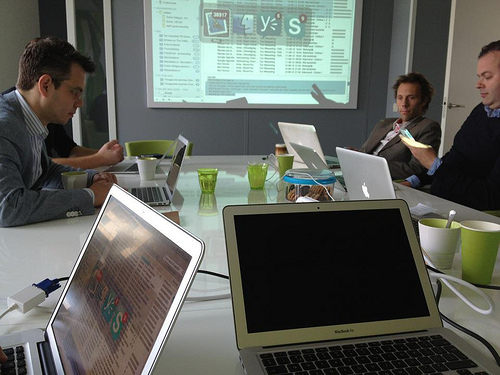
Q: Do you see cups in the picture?
A: Yes, there is a cup.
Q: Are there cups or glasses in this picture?
A: Yes, there is a cup.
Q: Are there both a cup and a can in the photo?
A: No, there is a cup but no cans.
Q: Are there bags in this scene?
A: No, there are no bags.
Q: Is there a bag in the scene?
A: No, there are no bags.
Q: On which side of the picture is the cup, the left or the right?
A: The cup is on the right of the image.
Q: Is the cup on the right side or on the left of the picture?
A: The cup is on the right of the image.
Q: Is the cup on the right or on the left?
A: The cup is on the right of the image.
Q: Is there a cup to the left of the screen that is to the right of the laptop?
A: No, the cup is to the right of the screen.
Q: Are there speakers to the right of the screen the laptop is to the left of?
A: No, there is a cup to the right of the screen.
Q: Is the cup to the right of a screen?
A: Yes, the cup is to the right of a screen.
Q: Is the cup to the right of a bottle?
A: No, the cup is to the right of a screen.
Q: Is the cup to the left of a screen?
A: No, the cup is to the right of a screen.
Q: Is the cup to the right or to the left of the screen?
A: The cup is to the right of the screen.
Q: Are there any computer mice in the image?
A: No, there are no computer mice.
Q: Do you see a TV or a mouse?
A: No, there are no computer mice or televisions.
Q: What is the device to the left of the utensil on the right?
A: The device is a screen.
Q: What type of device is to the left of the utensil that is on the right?
A: The device is a screen.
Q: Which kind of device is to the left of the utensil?
A: The device is a screen.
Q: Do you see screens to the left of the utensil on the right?
A: Yes, there is a screen to the left of the utensil.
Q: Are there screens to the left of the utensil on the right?
A: Yes, there is a screen to the left of the utensil.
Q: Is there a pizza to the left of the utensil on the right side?
A: No, there is a screen to the left of the utensil.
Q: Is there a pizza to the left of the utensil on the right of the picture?
A: No, there is a screen to the left of the utensil.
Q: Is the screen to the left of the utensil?
A: Yes, the screen is to the left of the utensil.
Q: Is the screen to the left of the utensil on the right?
A: Yes, the screen is to the left of the utensil.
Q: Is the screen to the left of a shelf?
A: No, the screen is to the left of the utensil.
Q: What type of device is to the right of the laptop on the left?
A: The device is a screen.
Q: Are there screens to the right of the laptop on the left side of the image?
A: Yes, there is a screen to the right of the laptop.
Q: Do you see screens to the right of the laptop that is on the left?
A: Yes, there is a screen to the right of the laptop.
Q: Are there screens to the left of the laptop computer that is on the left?
A: No, the screen is to the right of the laptop.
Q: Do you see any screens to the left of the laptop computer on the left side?
A: No, the screen is to the right of the laptop.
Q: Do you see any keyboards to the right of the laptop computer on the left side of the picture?
A: No, there is a screen to the right of the laptop.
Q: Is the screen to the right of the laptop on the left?
A: Yes, the screen is to the right of the laptop computer.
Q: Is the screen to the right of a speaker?
A: No, the screen is to the right of the laptop computer.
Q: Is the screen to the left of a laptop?
A: No, the screen is to the right of a laptop.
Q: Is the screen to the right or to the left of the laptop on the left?
A: The screen is to the right of the laptop computer.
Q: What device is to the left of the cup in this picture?
A: The device is a screen.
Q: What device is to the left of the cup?
A: The device is a screen.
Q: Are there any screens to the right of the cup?
A: No, the screen is to the left of the cup.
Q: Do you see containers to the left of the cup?
A: No, there is a screen to the left of the cup.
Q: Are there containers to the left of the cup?
A: No, there is a screen to the left of the cup.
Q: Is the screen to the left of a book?
A: No, the screen is to the left of the cup.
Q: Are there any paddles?
A: No, there are no paddles.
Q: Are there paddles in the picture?
A: No, there are no paddles.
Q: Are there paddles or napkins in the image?
A: No, there are no paddles or napkins.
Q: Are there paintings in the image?
A: No, there are no paintings.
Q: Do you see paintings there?
A: No, there are no paintings.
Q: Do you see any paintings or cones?
A: No, there are no paintings or cones.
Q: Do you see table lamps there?
A: No, there are no table lamps.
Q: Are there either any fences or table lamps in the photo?
A: No, there are no table lamps or fences.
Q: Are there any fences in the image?
A: No, there are no fences.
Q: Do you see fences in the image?
A: No, there are no fences.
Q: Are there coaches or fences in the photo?
A: No, there are no fences or coaches.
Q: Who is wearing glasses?
A: The man is wearing glasses.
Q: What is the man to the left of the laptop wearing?
A: The man is wearing glasses.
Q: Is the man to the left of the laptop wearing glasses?
A: Yes, the man is wearing glasses.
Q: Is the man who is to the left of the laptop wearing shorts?
A: No, the man is wearing glasses.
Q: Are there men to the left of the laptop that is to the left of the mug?
A: Yes, there is a man to the left of the laptop.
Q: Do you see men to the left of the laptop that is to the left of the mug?
A: Yes, there is a man to the left of the laptop.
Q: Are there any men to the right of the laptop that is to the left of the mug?
A: No, the man is to the left of the laptop.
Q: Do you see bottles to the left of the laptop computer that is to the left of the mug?
A: No, there is a man to the left of the laptop.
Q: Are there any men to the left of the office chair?
A: Yes, there is a man to the left of the office chair.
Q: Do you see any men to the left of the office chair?
A: Yes, there is a man to the left of the office chair.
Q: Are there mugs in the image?
A: Yes, there is a mug.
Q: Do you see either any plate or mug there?
A: Yes, there is a mug.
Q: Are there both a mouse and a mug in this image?
A: No, there is a mug but no computer mice.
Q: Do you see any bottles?
A: No, there are no bottles.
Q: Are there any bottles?
A: No, there are no bottles.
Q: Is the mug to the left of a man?
A: Yes, the mug is to the left of a man.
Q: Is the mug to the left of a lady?
A: No, the mug is to the left of a man.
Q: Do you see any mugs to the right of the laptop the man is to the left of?
A: Yes, there is a mug to the right of the laptop computer.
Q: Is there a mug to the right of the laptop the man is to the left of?
A: Yes, there is a mug to the right of the laptop computer.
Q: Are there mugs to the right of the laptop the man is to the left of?
A: Yes, there is a mug to the right of the laptop computer.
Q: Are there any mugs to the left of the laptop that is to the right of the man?
A: No, the mug is to the right of the laptop.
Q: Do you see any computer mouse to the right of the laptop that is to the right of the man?
A: No, there is a mug to the right of the laptop.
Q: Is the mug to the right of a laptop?
A: Yes, the mug is to the right of a laptop.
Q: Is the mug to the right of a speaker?
A: No, the mug is to the right of a laptop.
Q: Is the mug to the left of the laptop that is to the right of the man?
A: No, the mug is to the right of the laptop computer.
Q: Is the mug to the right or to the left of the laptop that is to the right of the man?
A: The mug is to the right of the laptop.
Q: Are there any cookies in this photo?
A: Yes, there are cookies.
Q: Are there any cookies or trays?
A: Yes, there are cookies.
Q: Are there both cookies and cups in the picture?
A: Yes, there are both cookies and a cup.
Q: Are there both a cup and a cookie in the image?
A: Yes, there are both a cookie and a cup.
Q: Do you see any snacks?
A: No, there are no snacks.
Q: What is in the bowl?
A: The cookies are in the bowl.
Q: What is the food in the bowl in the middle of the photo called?
A: The food is cookies.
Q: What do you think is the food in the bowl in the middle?
A: The food is cookies.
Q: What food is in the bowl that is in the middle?
A: The food is cookies.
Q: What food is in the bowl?
A: The food is cookies.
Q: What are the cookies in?
A: The cookies are in the bowl.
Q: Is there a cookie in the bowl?
A: Yes, there are cookies in the bowl.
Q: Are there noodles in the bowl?
A: No, there are cookies in the bowl.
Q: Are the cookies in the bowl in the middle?
A: Yes, the cookies are in the bowl.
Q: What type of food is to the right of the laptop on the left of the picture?
A: The food is cookies.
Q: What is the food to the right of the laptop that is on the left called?
A: The food is cookies.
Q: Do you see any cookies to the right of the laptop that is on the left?
A: Yes, there are cookies to the right of the laptop.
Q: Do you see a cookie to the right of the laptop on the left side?
A: Yes, there are cookies to the right of the laptop.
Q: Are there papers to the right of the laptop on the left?
A: No, there are cookies to the right of the laptop.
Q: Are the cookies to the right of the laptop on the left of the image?
A: Yes, the cookies are to the right of the laptop.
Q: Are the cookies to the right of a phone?
A: No, the cookies are to the right of the laptop.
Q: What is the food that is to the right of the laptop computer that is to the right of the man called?
A: The food is cookies.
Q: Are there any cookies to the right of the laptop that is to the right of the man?
A: Yes, there are cookies to the right of the laptop.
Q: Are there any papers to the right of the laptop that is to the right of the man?
A: No, there are cookies to the right of the laptop computer.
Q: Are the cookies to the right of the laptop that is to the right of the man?
A: Yes, the cookies are to the right of the laptop.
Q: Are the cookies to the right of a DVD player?
A: No, the cookies are to the right of the laptop.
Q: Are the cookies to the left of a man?
A: Yes, the cookies are to the left of a man.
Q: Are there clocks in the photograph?
A: No, there are no clocks.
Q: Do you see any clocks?
A: No, there are no clocks.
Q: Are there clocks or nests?
A: No, there are no clocks or nests.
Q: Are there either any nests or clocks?
A: No, there are no clocks or nests.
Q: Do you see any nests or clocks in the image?
A: No, there are no clocks or nests.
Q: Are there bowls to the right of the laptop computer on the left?
A: Yes, there is a bowl to the right of the laptop computer.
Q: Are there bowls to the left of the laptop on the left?
A: No, the bowl is to the right of the laptop.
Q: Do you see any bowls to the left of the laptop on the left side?
A: No, the bowl is to the right of the laptop.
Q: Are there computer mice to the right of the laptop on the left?
A: No, there is a bowl to the right of the laptop.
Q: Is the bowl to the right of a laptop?
A: Yes, the bowl is to the right of a laptop.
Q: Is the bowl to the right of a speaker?
A: No, the bowl is to the right of a laptop.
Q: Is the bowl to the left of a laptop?
A: No, the bowl is to the right of a laptop.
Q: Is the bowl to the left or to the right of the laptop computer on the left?
A: The bowl is to the right of the laptop.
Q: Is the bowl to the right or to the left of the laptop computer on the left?
A: The bowl is to the right of the laptop.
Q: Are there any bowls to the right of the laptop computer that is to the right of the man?
A: Yes, there is a bowl to the right of the laptop.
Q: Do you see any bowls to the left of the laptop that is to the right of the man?
A: No, the bowl is to the right of the laptop.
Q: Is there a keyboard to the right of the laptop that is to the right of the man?
A: No, there is a bowl to the right of the laptop.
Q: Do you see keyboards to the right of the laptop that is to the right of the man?
A: No, there is a bowl to the right of the laptop.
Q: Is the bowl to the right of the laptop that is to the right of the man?
A: Yes, the bowl is to the right of the laptop.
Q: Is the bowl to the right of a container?
A: No, the bowl is to the right of the laptop.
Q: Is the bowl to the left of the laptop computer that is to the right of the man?
A: No, the bowl is to the right of the laptop.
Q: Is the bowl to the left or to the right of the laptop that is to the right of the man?
A: The bowl is to the right of the laptop.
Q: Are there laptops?
A: Yes, there is a laptop.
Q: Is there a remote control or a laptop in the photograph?
A: Yes, there is a laptop.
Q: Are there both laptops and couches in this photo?
A: No, there is a laptop but no couches.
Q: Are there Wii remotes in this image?
A: No, there are no Wii remotes.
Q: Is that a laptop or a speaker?
A: That is a laptop.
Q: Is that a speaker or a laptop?
A: That is a laptop.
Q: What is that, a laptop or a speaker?
A: That is a laptop.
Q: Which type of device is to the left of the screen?
A: The device is a laptop.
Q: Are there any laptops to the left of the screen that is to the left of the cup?
A: Yes, there is a laptop to the left of the screen.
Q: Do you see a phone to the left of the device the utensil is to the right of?
A: No, there is a laptop to the left of the screen.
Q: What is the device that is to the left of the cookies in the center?
A: The device is a laptop.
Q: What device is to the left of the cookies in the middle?
A: The device is a laptop.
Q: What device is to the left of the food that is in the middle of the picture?
A: The device is a laptop.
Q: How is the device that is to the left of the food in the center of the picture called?
A: The device is a laptop.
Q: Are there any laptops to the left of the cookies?
A: Yes, there is a laptop to the left of the cookies.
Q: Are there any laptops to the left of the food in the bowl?
A: Yes, there is a laptop to the left of the cookies.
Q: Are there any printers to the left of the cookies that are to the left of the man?
A: No, there is a laptop to the left of the cookies.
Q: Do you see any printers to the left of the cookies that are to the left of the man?
A: No, there is a laptop to the left of the cookies.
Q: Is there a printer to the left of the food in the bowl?
A: No, there is a laptop to the left of the cookies.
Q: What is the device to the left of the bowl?
A: The device is a laptop.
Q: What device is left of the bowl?
A: The device is a laptop.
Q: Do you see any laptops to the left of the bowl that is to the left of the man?
A: Yes, there is a laptop to the left of the bowl.